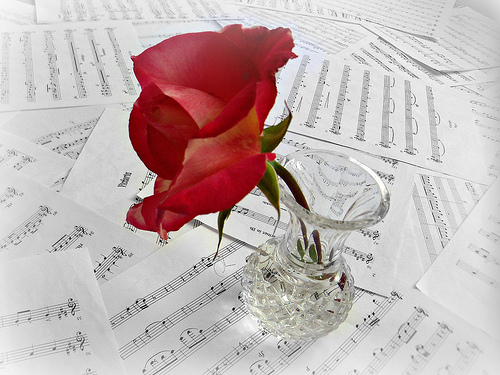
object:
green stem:
[263, 151, 335, 274]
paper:
[0, 0, 500, 373]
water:
[241, 232, 354, 339]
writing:
[0, 0, 500, 375]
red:
[155, 42, 228, 85]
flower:
[122, 23, 392, 337]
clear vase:
[242, 145, 383, 347]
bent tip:
[283, 99, 291, 115]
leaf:
[261, 100, 292, 152]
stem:
[255, 148, 341, 295]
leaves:
[214, 208, 226, 260]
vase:
[240, 143, 391, 345]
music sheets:
[0, 1, 499, 373]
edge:
[227, 18, 295, 105]